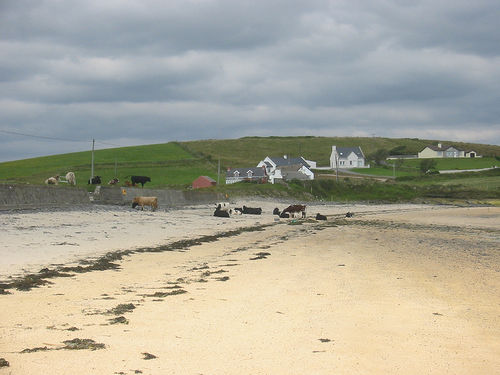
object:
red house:
[191, 174, 216, 189]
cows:
[277, 204, 310, 221]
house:
[222, 165, 270, 186]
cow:
[62, 169, 78, 185]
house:
[417, 141, 447, 159]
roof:
[416, 141, 441, 151]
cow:
[88, 174, 105, 187]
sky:
[0, 0, 500, 164]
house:
[329, 144, 367, 168]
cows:
[315, 211, 329, 221]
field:
[0, 135, 500, 198]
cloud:
[0, 47, 492, 109]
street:
[437, 165, 500, 174]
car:
[425, 168, 441, 175]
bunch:
[1, 220, 284, 297]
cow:
[45, 175, 61, 186]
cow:
[129, 174, 154, 190]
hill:
[0, 135, 500, 201]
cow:
[130, 194, 161, 213]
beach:
[0, 197, 500, 375]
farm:
[326, 143, 371, 171]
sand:
[2, 203, 500, 373]